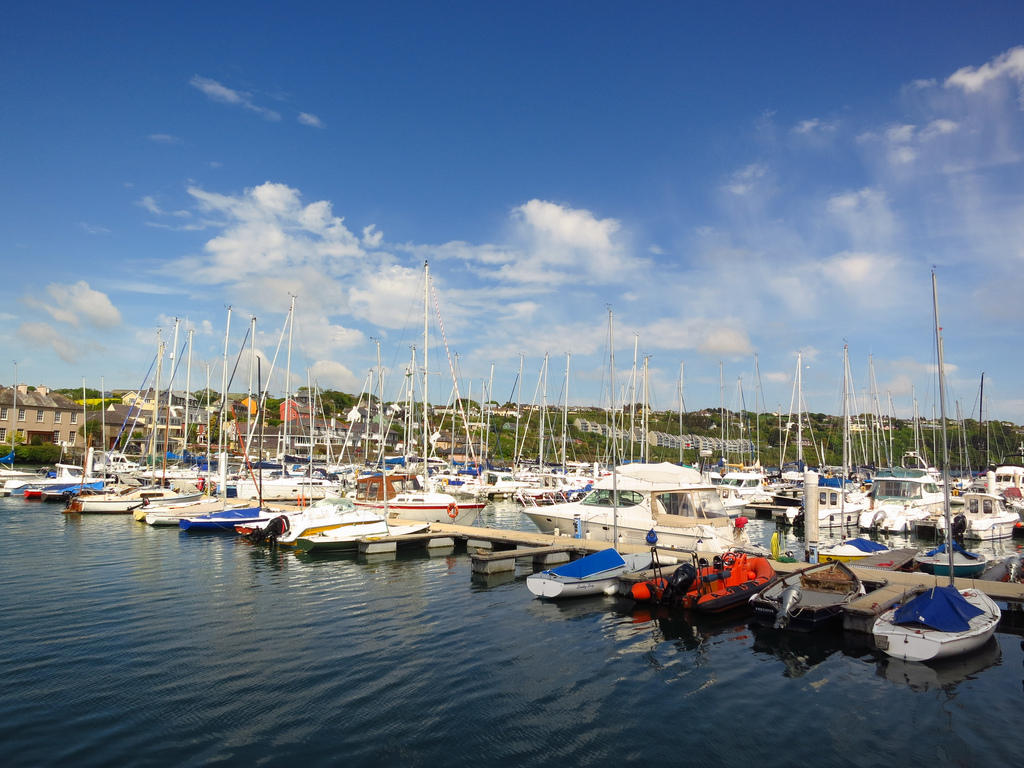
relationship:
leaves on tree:
[886, 420, 915, 434] [882, 411, 911, 466]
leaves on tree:
[543, 407, 556, 418] [517, 396, 567, 448]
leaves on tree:
[810, 418, 832, 440] [795, 392, 845, 462]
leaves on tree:
[880, 424, 919, 444] [866, 417, 923, 480]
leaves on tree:
[657, 413, 738, 433] [663, 411, 733, 466]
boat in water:
[640, 541, 733, 617] [471, 660, 793, 736]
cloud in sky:
[460, 217, 607, 293] [352, 76, 733, 176]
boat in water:
[869, 573, 990, 660] [277, 608, 558, 742]